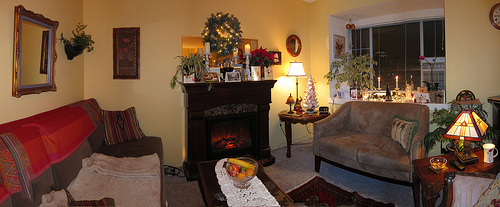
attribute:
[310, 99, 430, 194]
sofa — suede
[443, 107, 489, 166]
lamp — on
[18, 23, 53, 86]
mirror — framed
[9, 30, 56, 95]
mirror — framed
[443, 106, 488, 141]
glass lampshade — stained glass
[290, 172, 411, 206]
rug — small, area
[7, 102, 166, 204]
love seat — beige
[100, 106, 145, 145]
pillow — striped, throw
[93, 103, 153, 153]
pillow — colorful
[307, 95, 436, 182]
sofa — brown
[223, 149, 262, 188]
bowl — glass